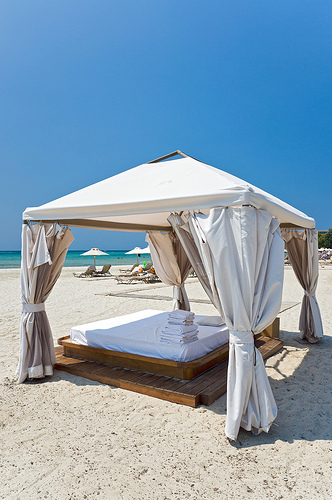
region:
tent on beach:
[20, 139, 297, 478]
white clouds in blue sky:
[12, 12, 61, 67]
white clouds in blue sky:
[7, 75, 53, 113]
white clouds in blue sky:
[30, 103, 68, 150]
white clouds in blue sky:
[75, 31, 114, 86]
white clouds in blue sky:
[104, 35, 152, 101]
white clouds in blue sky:
[165, 13, 230, 62]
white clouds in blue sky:
[175, 86, 225, 128]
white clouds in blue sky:
[243, 111, 287, 168]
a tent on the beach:
[12, 132, 326, 445]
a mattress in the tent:
[65, 288, 229, 367]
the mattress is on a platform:
[49, 295, 282, 409]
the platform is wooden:
[55, 328, 289, 412]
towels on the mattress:
[154, 306, 202, 349]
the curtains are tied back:
[9, 216, 322, 442]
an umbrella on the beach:
[71, 244, 115, 279]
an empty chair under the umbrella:
[75, 264, 108, 279]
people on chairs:
[122, 259, 158, 295]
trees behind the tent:
[313, 228, 331, 252]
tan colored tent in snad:
[33, 152, 299, 456]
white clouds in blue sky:
[36, 28, 90, 82]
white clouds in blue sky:
[18, 61, 70, 110]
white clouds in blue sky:
[75, 78, 119, 109]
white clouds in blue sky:
[18, 90, 56, 132]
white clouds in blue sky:
[45, 106, 107, 164]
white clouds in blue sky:
[109, 4, 163, 43]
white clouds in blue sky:
[79, 228, 115, 252]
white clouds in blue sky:
[177, 87, 249, 147]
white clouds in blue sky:
[253, 48, 295, 107]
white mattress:
[123, 308, 201, 360]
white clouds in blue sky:
[16, 34, 55, 89]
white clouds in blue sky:
[6, 130, 60, 190]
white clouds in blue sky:
[73, 103, 121, 139]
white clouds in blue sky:
[138, 100, 183, 136]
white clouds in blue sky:
[194, 18, 249, 93]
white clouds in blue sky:
[240, 93, 276, 157]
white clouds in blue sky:
[66, 64, 111, 116]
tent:
[52, 139, 286, 267]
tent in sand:
[21, 114, 316, 473]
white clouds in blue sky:
[66, 26, 136, 118]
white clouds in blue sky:
[166, 18, 208, 82]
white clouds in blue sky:
[226, 0, 270, 55]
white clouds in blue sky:
[269, 103, 304, 199]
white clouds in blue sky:
[80, 18, 144, 89]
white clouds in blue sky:
[97, 102, 161, 126]